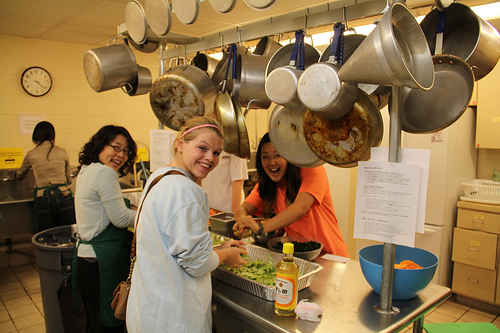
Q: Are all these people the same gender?
A: Yes, all the people are female.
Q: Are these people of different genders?
A: No, all the people are female.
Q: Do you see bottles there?
A: Yes, there is a bottle.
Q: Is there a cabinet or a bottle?
A: Yes, there is a bottle.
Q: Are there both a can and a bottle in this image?
A: No, there is a bottle but no cans.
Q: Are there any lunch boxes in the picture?
A: No, there are no lunch boxes.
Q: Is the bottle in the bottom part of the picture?
A: Yes, the bottle is in the bottom of the image.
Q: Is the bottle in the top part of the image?
A: No, the bottle is in the bottom of the image.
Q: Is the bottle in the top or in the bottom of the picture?
A: The bottle is in the bottom of the image.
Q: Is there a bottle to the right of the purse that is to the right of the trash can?
A: Yes, there is a bottle to the right of the purse.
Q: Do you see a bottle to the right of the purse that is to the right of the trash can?
A: Yes, there is a bottle to the right of the purse.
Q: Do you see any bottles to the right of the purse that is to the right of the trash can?
A: Yes, there is a bottle to the right of the purse.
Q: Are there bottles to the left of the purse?
A: No, the bottle is to the right of the purse.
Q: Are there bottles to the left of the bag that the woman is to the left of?
A: No, the bottle is to the right of the purse.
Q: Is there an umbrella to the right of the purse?
A: No, there is a bottle to the right of the purse.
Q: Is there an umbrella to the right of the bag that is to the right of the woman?
A: No, there is a bottle to the right of the purse.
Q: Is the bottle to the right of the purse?
A: Yes, the bottle is to the right of the purse.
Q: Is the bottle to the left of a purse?
A: No, the bottle is to the right of a purse.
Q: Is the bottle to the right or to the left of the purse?
A: The bottle is to the right of the purse.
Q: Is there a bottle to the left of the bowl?
A: Yes, there is a bottle to the left of the bowl.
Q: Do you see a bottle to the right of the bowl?
A: No, the bottle is to the left of the bowl.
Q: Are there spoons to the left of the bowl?
A: No, there is a bottle to the left of the bowl.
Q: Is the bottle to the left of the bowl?
A: Yes, the bottle is to the left of the bowl.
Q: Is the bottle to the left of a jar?
A: No, the bottle is to the left of the bowl.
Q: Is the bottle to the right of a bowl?
A: No, the bottle is to the left of a bowl.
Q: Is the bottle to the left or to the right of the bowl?
A: The bottle is to the left of the bowl.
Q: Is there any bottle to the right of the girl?
A: Yes, there is a bottle to the right of the girl.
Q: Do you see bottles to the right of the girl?
A: Yes, there is a bottle to the right of the girl.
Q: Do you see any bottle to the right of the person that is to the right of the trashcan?
A: Yes, there is a bottle to the right of the girl.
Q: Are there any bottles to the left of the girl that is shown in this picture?
A: No, the bottle is to the right of the girl.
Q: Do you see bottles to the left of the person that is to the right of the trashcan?
A: No, the bottle is to the right of the girl.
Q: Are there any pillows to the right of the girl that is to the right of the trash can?
A: No, there is a bottle to the right of the girl.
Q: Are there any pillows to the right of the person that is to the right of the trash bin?
A: No, there is a bottle to the right of the girl.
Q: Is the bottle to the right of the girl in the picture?
A: Yes, the bottle is to the right of the girl.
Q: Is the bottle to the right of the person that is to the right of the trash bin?
A: Yes, the bottle is to the right of the girl.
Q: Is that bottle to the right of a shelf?
A: No, the bottle is to the right of the girl.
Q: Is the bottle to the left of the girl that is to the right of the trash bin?
A: No, the bottle is to the right of the girl.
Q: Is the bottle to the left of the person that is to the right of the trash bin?
A: No, the bottle is to the right of the girl.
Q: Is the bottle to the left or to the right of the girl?
A: The bottle is to the right of the girl.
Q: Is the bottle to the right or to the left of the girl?
A: The bottle is to the right of the girl.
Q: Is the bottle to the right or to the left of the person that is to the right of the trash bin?
A: The bottle is to the right of the girl.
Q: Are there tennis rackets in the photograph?
A: No, there are no tennis rackets.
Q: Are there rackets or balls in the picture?
A: No, there are no rackets or balls.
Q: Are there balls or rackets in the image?
A: No, there are no rackets or balls.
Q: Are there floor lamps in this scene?
A: No, there are no floor lamps.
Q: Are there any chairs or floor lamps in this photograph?
A: No, there are no floor lamps or chairs.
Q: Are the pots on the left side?
A: Yes, the pots are on the left of the image.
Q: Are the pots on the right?
A: No, the pots are on the left of the image.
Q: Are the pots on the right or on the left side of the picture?
A: The pots are on the left of the image.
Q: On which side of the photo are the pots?
A: The pots are on the left of the image.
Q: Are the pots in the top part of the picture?
A: Yes, the pots are in the top of the image.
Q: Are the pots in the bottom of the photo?
A: No, the pots are in the top of the image.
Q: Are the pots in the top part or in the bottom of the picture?
A: The pots are in the top of the image.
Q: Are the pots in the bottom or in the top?
A: The pots are in the top of the image.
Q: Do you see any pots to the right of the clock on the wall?
A: Yes, there are pots to the right of the clock.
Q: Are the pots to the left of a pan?
A: Yes, the pots are to the left of a pan.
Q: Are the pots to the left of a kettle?
A: No, the pots are to the left of a pan.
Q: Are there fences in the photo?
A: No, there are no fences.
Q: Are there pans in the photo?
A: Yes, there is a pan.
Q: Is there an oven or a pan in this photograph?
A: Yes, there is a pan.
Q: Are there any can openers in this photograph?
A: No, there are no can openers.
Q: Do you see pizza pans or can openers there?
A: No, there are no can openers or pizza pans.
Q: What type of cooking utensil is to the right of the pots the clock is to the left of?
A: The cooking utensil is a pan.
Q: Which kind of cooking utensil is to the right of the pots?
A: The cooking utensil is a pan.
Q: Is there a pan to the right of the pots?
A: Yes, there is a pan to the right of the pots.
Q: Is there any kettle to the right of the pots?
A: No, there is a pan to the right of the pots.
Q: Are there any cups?
A: No, there are no cups.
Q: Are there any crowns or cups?
A: No, there are no cups or crowns.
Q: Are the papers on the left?
A: No, the papers are on the right of the image.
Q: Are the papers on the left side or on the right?
A: The papers are on the right of the image.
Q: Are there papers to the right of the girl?
A: Yes, there are papers to the right of the girl.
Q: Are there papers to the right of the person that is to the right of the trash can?
A: Yes, there are papers to the right of the girl.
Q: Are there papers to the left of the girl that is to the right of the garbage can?
A: No, the papers are to the right of the girl.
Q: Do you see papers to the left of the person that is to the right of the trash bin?
A: No, the papers are to the right of the girl.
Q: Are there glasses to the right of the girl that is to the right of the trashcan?
A: No, there are papers to the right of the girl.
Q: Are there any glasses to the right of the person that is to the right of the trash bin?
A: No, there are papers to the right of the girl.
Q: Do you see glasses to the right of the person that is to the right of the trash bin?
A: No, there are papers to the right of the girl.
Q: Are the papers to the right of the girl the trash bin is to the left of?
A: Yes, the papers are to the right of the girl.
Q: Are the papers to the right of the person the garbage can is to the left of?
A: Yes, the papers are to the right of the girl.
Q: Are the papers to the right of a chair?
A: No, the papers are to the right of the girl.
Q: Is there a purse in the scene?
A: Yes, there is a purse.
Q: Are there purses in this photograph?
A: Yes, there is a purse.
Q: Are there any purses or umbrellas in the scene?
A: Yes, there is a purse.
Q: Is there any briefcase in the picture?
A: No, there are no briefcases.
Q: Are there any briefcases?
A: No, there are no briefcases.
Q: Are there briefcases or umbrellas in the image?
A: No, there are no briefcases or umbrellas.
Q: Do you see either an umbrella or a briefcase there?
A: No, there are no briefcases or umbrellas.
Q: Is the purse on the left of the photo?
A: Yes, the purse is on the left of the image.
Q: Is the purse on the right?
A: No, the purse is on the left of the image.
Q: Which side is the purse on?
A: The purse is on the left of the image.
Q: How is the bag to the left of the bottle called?
A: The bag is a purse.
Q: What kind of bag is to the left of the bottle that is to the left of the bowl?
A: The bag is a purse.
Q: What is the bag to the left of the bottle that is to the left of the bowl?
A: The bag is a purse.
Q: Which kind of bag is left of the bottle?
A: The bag is a purse.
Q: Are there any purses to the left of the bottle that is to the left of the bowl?
A: Yes, there is a purse to the left of the bottle.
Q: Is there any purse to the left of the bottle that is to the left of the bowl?
A: Yes, there is a purse to the left of the bottle.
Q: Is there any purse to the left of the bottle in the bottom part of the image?
A: Yes, there is a purse to the left of the bottle.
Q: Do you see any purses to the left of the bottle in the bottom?
A: Yes, there is a purse to the left of the bottle.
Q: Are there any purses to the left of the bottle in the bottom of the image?
A: Yes, there is a purse to the left of the bottle.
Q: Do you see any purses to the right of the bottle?
A: No, the purse is to the left of the bottle.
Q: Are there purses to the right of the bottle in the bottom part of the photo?
A: No, the purse is to the left of the bottle.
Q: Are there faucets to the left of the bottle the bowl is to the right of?
A: No, there is a purse to the left of the bottle.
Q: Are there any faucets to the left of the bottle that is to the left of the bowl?
A: No, there is a purse to the left of the bottle.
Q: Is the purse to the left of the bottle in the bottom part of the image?
A: Yes, the purse is to the left of the bottle.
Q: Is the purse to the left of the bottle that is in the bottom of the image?
A: Yes, the purse is to the left of the bottle.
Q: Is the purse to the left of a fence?
A: No, the purse is to the left of the bottle.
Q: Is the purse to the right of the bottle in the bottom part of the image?
A: No, the purse is to the left of the bottle.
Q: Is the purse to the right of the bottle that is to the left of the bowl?
A: No, the purse is to the left of the bottle.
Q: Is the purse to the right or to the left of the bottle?
A: The purse is to the left of the bottle.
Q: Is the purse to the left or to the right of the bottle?
A: The purse is to the left of the bottle.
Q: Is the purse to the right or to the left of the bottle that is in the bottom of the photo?
A: The purse is to the left of the bottle.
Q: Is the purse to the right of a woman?
A: Yes, the purse is to the right of a woman.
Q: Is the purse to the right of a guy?
A: No, the purse is to the right of a woman.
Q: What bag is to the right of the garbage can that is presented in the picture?
A: The bag is a purse.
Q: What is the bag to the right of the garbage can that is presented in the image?
A: The bag is a purse.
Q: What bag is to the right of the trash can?
A: The bag is a purse.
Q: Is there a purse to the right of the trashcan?
A: Yes, there is a purse to the right of the trashcan.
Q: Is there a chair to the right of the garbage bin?
A: No, there is a purse to the right of the garbage bin.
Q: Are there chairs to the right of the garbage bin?
A: No, there is a purse to the right of the garbage bin.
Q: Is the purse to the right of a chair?
A: No, the purse is to the right of the trashcan.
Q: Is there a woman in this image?
A: Yes, there is a woman.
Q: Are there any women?
A: Yes, there is a woman.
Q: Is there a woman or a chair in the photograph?
A: Yes, there is a woman.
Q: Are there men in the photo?
A: No, there are no men.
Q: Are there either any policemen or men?
A: No, there are no men or policemen.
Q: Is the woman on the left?
A: Yes, the woman is on the left of the image.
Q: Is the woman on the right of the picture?
A: No, the woman is on the left of the image.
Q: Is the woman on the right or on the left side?
A: The woman is on the left of the image.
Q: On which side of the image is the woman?
A: The woman is on the left of the image.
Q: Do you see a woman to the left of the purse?
A: Yes, there is a woman to the left of the purse.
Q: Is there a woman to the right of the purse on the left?
A: No, the woman is to the left of the purse.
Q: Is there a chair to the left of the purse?
A: No, there is a woman to the left of the purse.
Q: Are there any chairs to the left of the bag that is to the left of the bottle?
A: No, there is a woman to the left of the purse.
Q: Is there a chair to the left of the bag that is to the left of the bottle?
A: No, there is a woman to the left of the purse.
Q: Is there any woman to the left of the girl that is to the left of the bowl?
A: Yes, there is a woman to the left of the girl.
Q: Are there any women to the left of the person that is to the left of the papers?
A: Yes, there is a woman to the left of the girl.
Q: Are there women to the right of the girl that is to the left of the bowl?
A: No, the woman is to the left of the girl.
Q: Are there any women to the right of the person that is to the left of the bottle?
A: No, the woman is to the left of the girl.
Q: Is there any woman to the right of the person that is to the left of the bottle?
A: No, the woman is to the left of the girl.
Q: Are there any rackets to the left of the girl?
A: No, there is a woman to the left of the girl.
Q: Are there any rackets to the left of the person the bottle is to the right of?
A: No, there is a woman to the left of the girl.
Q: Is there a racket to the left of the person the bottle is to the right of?
A: No, there is a woman to the left of the girl.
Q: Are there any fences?
A: No, there are no fences.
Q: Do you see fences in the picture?
A: No, there are no fences.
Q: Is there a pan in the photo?
A: Yes, there is a pan.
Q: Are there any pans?
A: Yes, there is a pan.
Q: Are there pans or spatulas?
A: Yes, there is a pan.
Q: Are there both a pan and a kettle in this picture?
A: No, there is a pan but no kettles.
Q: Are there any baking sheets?
A: No, there are no baking sheets.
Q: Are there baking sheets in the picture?
A: No, there are no baking sheets.